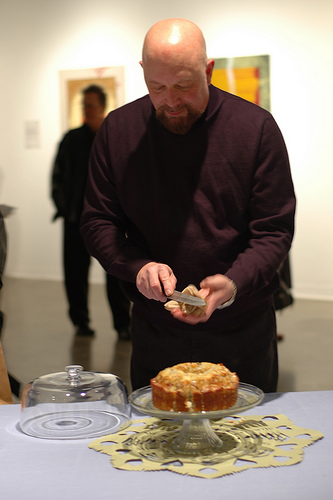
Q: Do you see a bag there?
A: No, there are no bags.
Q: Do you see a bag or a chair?
A: No, there are no bags or chairs.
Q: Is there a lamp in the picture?
A: No, there are no lamps.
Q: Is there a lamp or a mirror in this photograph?
A: No, there are no lamps or mirrors.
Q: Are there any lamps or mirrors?
A: No, there are no lamps or mirrors.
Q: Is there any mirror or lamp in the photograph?
A: No, there are no lamps or mirrors.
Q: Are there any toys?
A: No, there are no toys.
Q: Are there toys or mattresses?
A: No, there are no toys or mattresses.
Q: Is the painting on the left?
A: Yes, the painting is on the left of the image.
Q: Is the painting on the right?
A: No, the painting is on the left of the image.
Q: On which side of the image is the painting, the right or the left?
A: The painting is on the left of the image.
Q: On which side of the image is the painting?
A: The painting is on the left of the image.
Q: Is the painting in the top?
A: Yes, the painting is in the top of the image.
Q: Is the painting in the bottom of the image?
A: No, the painting is in the top of the image.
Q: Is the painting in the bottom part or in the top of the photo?
A: The painting is in the top of the image.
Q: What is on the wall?
A: The painting is on the wall.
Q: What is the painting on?
A: The painting is on the wall.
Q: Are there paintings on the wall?
A: Yes, there is a painting on the wall.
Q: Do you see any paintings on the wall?
A: Yes, there is a painting on the wall.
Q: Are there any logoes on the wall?
A: No, there is a painting on the wall.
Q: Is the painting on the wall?
A: Yes, the painting is on the wall.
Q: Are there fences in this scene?
A: No, there are no fences.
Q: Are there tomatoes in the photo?
A: No, there are no tomatoes.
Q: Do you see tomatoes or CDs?
A: No, there are no tomatoes or cds.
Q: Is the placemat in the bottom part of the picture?
A: Yes, the placemat is in the bottom of the image.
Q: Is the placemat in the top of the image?
A: No, the placemat is in the bottom of the image.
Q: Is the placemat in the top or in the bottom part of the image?
A: The placemat is in the bottom of the image.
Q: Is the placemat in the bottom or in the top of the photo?
A: The placemat is in the bottom of the image.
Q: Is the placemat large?
A: Yes, the placemat is large.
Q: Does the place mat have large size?
A: Yes, the place mat is large.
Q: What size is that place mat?
A: The place mat is large.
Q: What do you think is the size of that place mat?
A: The place mat is large.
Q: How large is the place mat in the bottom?
A: The placemat is large.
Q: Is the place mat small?
A: No, the place mat is large.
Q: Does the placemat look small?
A: No, the placemat is large.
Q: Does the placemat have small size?
A: No, the placemat is large.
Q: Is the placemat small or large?
A: The placemat is large.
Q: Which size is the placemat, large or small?
A: The placemat is large.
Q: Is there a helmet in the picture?
A: No, there are no helmets.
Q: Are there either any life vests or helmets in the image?
A: No, there are no helmets or life vests.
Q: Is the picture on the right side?
A: Yes, the picture is on the right of the image.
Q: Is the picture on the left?
A: No, the picture is on the right of the image.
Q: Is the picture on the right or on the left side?
A: The picture is on the right of the image.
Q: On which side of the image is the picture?
A: The picture is on the right of the image.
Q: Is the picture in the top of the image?
A: Yes, the picture is in the top of the image.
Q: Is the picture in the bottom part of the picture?
A: No, the picture is in the top of the image.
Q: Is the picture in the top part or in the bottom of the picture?
A: The picture is in the top of the image.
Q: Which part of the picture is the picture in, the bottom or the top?
A: The picture is in the top of the image.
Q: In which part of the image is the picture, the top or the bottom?
A: The picture is in the top of the image.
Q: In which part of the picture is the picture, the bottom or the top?
A: The picture is in the top of the image.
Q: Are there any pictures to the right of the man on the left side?
A: Yes, there is a picture to the right of the man.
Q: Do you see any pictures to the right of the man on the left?
A: Yes, there is a picture to the right of the man.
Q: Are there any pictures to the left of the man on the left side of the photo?
A: No, the picture is to the right of the man.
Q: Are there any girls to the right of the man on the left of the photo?
A: No, there is a picture to the right of the man.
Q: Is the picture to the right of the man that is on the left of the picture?
A: Yes, the picture is to the right of the man.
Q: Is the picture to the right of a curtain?
A: No, the picture is to the right of the man.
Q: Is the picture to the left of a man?
A: No, the picture is to the right of a man.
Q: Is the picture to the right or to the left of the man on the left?
A: The picture is to the right of the man.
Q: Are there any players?
A: No, there are no players.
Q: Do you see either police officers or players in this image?
A: No, there are no players or police officers.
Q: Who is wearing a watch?
A: The man is wearing a watch.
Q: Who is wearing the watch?
A: The man is wearing a watch.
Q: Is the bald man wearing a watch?
A: Yes, the man is wearing a watch.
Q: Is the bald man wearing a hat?
A: No, the man is wearing a watch.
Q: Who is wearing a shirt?
A: The man is wearing a shirt.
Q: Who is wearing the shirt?
A: The man is wearing a shirt.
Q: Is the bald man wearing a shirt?
A: Yes, the man is wearing a shirt.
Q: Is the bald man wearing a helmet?
A: No, the man is wearing a shirt.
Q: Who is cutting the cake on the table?
A: The man is cutting the cake.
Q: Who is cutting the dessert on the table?
A: The man is cutting the cake.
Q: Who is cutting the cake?
A: The man is cutting the cake.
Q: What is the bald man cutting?
A: The man is cutting the cake.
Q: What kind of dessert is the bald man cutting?
A: The man is cutting the cake.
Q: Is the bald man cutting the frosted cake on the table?
A: Yes, the man is cutting the cake.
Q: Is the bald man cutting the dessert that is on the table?
A: Yes, the man is cutting the cake.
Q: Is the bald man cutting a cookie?
A: No, the man is cutting the cake.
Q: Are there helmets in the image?
A: No, there are no helmets.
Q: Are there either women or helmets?
A: No, there are no helmets or women.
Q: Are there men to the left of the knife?
A: Yes, there is a man to the left of the knife.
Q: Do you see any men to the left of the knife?
A: Yes, there is a man to the left of the knife.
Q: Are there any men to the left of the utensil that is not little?
A: Yes, there is a man to the left of the knife.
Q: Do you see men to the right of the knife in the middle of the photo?
A: No, the man is to the left of the knife.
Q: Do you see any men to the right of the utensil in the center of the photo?
A: No, the man is to the left of the knife.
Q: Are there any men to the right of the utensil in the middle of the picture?
A: No, the man is to the left of the knife.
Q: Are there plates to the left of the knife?
A: No, there is a man to the left of the knife.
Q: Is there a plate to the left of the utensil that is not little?
A: No, there is a man to the left of the knife.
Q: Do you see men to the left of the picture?
A: Yes, there is a man to the left of the picture.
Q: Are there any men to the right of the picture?
A: No, the man is to the left of the picture.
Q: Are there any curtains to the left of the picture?
A: No, there is a man to the left of the picture.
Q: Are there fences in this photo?
A: No, there are no fences.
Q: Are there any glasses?
A: No, there are no glasses.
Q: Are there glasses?
A: No, there are no glasses.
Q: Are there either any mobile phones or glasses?
A: No, there are no glasses or mobile phones.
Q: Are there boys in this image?
A: No, there are no boys.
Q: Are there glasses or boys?
A: No, there are no boys or glasses.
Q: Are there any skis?
A: No, there are no skis.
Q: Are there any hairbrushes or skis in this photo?
A: No, there are no skis or hairbrushes.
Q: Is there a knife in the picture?
A: Yes, there is a knife.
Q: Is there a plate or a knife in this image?
A: Yes, there is a knife.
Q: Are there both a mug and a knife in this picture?
A: No, there is a knife but no mugs.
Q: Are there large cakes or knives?
A: Yes, there is a large knife.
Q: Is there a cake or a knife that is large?
A: Yes, the knife is large.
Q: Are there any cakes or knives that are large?
A: Yes, the knife is large.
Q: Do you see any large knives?
A: Yes, there is a large knife.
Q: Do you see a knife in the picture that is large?
A: Yes, there is a knife that is large.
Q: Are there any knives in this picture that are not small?
A: Yes, there is a large knife.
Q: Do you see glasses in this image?
A: No, there are no glasses.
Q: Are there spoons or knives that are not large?
A: No, there is a knife but it is large.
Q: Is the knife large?
A: Yes, the knife is large.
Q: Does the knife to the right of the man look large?
A: Yes, the knife is large.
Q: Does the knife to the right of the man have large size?
A: Yes, the knife is large.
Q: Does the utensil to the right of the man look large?
A: Yes, the knife is large.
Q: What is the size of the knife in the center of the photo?
A: The knife is large.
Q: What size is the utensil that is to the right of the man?
A: The knife is large.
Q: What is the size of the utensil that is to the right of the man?
A: The knife is large.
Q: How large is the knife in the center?
A: The knife is large.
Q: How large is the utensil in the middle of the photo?
A: The knife is large.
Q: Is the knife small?
A: No, the knife is large.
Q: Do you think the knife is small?
A: No, the knife is large.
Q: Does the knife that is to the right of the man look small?
A: No, the knife is large.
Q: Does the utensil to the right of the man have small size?
A: No, the knife is large.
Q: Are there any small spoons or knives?
A: No, there is a knife but it is large.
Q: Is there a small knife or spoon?
A: No, there is a knife but it is large.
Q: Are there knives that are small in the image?
A: No, there is a knife but it is large.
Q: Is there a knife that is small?
A: No, there is a knife but it is large.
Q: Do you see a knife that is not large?
A: No, there is a knife but it is large.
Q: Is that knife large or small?
A: The knife is large.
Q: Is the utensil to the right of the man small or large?
A: The knife is large.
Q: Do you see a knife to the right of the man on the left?
A: Yes, there is a knife to the right of the man.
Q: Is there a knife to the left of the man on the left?
A: No, the knife is to the right of the man.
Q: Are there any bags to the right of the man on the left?
A: No, there is a knife to the right of the man.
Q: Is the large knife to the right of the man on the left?
A: Yes, the knife is to the right of the man.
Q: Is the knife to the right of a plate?
A: No, the knife is to the right of the man.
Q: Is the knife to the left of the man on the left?
A: No, the knife is to the right of the man.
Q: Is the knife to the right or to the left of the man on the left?
A: The knife is to the right of the man.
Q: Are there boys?
A: No, there are no boys.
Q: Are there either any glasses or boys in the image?
A: No, there are no boys or glasses.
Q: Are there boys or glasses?
A: No, there are no boys or glasses.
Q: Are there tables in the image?
A: Yes, there is a table.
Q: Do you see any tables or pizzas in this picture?
A: Yes, there is a table.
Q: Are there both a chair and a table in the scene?
A: No, there is a table but no chairs.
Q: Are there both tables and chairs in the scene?
A: No, there is a table but no chairs.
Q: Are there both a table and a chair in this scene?
A: No, there is a table but no chairs.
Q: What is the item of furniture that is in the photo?
A: The piece of furniture is a table.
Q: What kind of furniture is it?
A: The piece of furniture is a table.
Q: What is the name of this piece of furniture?
A: This is a table.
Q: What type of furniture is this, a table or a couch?
A: This is a table.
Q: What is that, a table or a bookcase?
A: That is a table.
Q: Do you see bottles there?
A: No, there are no bottles.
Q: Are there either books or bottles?
A: No, there are no bottles or books.